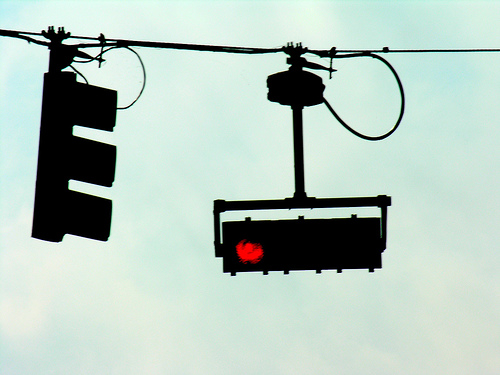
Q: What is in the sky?
A: White clouds.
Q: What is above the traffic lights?
A: Large black round wires.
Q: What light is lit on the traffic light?
A: Red.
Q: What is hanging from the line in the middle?
A: Traffic light?.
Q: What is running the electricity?
A: The lines attached.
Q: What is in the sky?
A: Nothing.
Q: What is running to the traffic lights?
A: Cable.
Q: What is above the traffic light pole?
A: Connector.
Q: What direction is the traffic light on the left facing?
A: Right.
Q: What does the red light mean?
A: Stop.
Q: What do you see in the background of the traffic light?
A: The sky.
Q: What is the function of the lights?
A: To control the flow of traffic.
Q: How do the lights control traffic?
A: By changing colors.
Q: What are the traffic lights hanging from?
A: A wire.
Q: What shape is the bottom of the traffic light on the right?
A: Rectangular.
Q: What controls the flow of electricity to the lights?
A: Wires.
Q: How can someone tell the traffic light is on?
A: The bulb is lit.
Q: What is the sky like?
A: Overcast.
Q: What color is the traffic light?
A: Black.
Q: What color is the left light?
A: Red.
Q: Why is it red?
A: To stop.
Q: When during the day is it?
A: Afternoon.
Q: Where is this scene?
A: Traffic light.